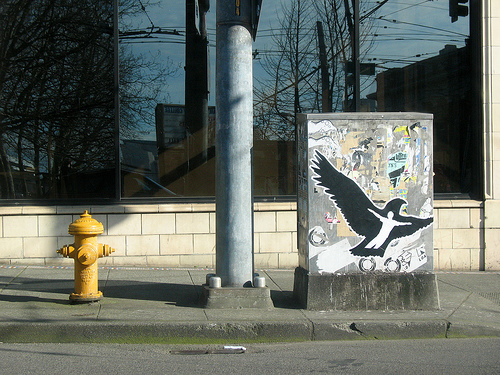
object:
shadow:
[0, 273, 298, 308]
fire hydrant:
[54, 208, 116, 304]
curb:
[0, 321, 500, 345]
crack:
[331, 321, 364, 335]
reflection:
[0, 0, 482, 203]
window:
[0, 0, 487, 206]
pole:
[216, 0, 253, 287]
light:
[447, 0, 472, 24]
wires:
[111, 0, 476, 66]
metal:
[290, 113, 441, 308]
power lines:
[117, 0, 471, 69]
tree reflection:
[0, 0, 182, 200]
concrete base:
[198, 281, 276, 310]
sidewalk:
[1, 265, 497, 373]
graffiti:
[308, 120, 434, 275]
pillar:
[290, 111, 437, 314]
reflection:
[184, 0, 216, 163]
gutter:
[168, 345, 245, 356]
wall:
[0, 193, 500, 268]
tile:
[140, 212, 177, 234]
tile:
[438, 209, 469, 229]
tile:
[18, 236, 60, 257]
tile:
[190, 233, 214, 257]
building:
[0, 1, 499, 269]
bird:
[308, 147, 434, 258]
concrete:
[2, 261, 500, 375]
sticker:
[307, 147, 433, 258]